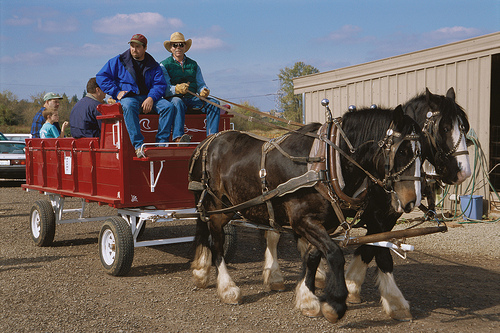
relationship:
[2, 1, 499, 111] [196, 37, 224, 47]
sky with clouds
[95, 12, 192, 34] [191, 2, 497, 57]
cloud in sky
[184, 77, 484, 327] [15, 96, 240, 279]
horses pulling cart